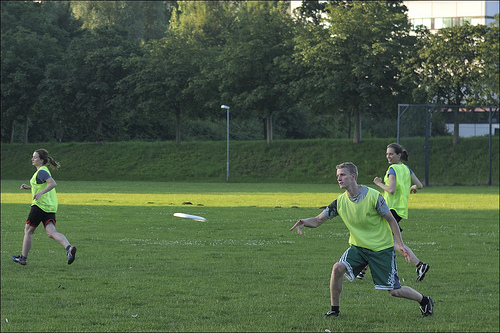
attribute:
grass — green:
[3, 178, 499, 327]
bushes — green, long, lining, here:
[1, 138, 498, 185]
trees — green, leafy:
[2, 1, 496, 136]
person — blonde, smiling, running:
[292, 160, 437, 319]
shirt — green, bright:
[336, 192, 396, 251]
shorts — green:
[339, 240, 404, 292]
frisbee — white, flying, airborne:
[172, 208, 206, 226]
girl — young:
[11, 143, 79, 268]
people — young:
[12, 143, 441, 319]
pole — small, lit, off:
[217, 101, 235, 183]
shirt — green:
[27, 170, 60, 214]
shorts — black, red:
[23, 201, 61, 228]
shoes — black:
[393, 208, 407, 235]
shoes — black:
[314, 299, 434, 322]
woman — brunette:
[16, 144, 75, 275]